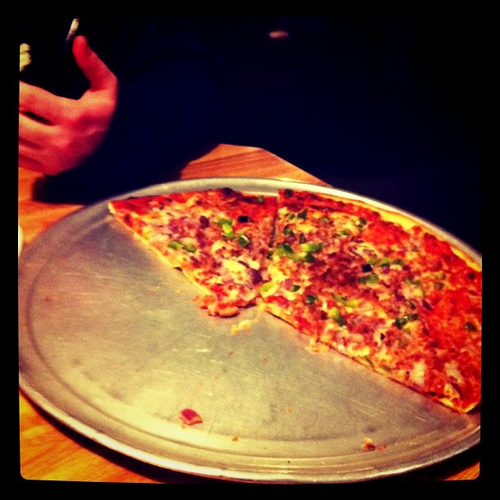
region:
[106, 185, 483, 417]
Four slices of pizza are left.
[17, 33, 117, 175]
Someone's hand is in the background.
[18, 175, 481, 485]
The pizza is on a metal pan.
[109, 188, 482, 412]
The pizza is half eaten.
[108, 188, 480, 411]
The pizza has peppers on top.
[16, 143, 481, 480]
A wooden table is under the pan.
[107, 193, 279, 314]
The pizza slice is slightly moved from the rest.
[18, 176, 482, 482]
The pizza pan is shiny.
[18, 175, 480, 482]
The pizza pan is circular.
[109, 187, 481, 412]
There are four pizza slices left.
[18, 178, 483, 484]
Half eaten pizza on pan.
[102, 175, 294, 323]
slice of pizza top left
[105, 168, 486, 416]
half pizza on pizza pan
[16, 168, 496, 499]
silver pizza baking pan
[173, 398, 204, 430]
piece of topping on pan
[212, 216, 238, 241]
piece of diced green pepper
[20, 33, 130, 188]
white person's left hand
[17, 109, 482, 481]
brown wooden table top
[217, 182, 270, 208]
char bubble on pizza crust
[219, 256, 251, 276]
melted mozzarella cheese on pizza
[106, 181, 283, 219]
thin rolled pizza crust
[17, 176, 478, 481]
Baked pizza resting on metal pan.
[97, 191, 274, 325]
a slice of pizza on a pan.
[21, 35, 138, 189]
a human hand near a pizza.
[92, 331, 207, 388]
a section of a pizza pan.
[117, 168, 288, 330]
toppings on a slice of pizza.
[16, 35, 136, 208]
A right human hand with finger nails.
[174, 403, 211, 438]
a piece of pizza on a tray.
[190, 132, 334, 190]
a section of a brown wooden table.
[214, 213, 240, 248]
green topping on a pizza.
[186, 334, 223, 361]
a knick in a metal pizza pan.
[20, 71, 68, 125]
a human pointer finger.